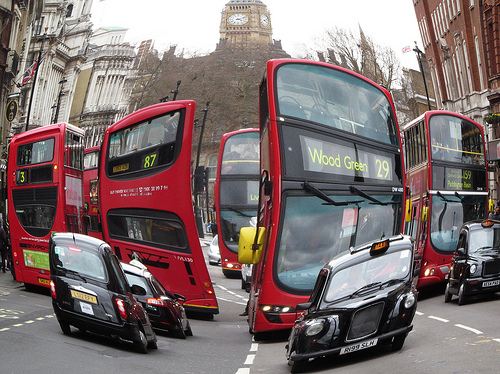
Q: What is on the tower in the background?
A: Clock.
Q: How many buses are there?
A: Six.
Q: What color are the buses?
A: Red.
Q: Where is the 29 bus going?
A: Wood Green.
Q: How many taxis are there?
A: Three.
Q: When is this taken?
A: Day time.